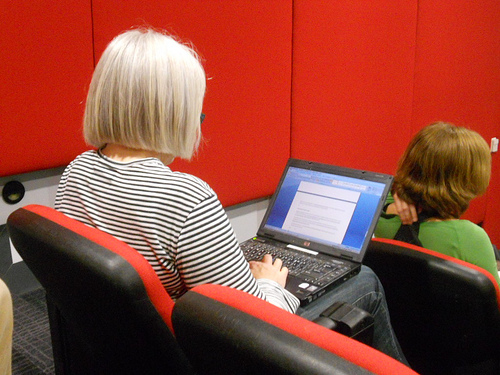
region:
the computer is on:
[245, 127, 390, 275]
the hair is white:
[80, 18, 212, 160]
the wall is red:
[245, 37, 403, 127]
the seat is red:
[32, 197, 182, 309]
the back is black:
[12, 207, 168, 363]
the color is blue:
[325, 180, 393, 262]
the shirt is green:
[357, 187, 494, 277]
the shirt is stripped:
[101, 160, 219, 259]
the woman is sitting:
[44, 20, 331, 374]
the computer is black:
[257, 142, 384, 300]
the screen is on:
[265, 147, 382, 261]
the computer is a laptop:
[234, 125, 392, 324]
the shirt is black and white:
[82, 141, 228, 281]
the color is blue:
[348, 188, 383, 262]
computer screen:
[248, 157, 404, 252]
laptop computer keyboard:
[233, 228, 363, 296]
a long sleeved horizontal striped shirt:
[31, 135, 303, 335]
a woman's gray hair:
[72, 0, 222, 171]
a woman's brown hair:
[385, 102, 495, 235]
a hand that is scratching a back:
[371, 160, 453, 230]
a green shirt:
[361, 176, 497, 278]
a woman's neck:
[80, 128, 170, 173]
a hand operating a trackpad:
[240, 242, 297, 294]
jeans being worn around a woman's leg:
[282, 239, 427, 374]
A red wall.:
[208, 1, 496, 123]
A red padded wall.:
[206, 1, 493, 118]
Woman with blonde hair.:
[37, 12, 234, 257]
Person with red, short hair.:
[384, 109, 495, 253]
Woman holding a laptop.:
[62, 15, 406, 345]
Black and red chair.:
[6, 171, 183, 371]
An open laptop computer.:
[235, 134, 397, 299]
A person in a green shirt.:
[390, 110, 495, 275]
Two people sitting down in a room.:
[23, 20, 494, 312]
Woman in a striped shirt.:
[55, 30, 258, 307]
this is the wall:
[218, 17, 292, 92]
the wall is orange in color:
[323, 21, 466, 86]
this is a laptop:
[268, 156, 388, 264]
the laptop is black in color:
[262, 161, 374, 263]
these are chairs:
[10, 199, 307, 374]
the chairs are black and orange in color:
[25, 207, 192, 373]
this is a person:
[76, 150, 258, 257]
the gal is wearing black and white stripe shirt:
[87, 150, 254, 265]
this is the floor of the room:
[18, 316, 46, 373]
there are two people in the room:
[90, 77, 494, 265]